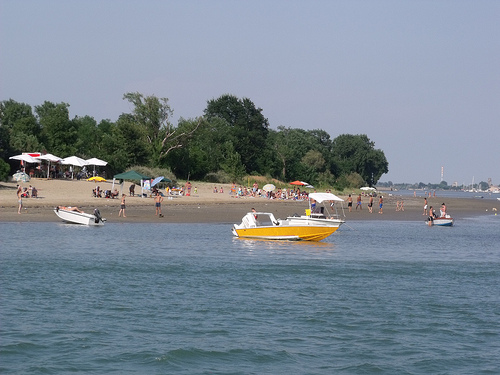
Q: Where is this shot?
A: At a beach.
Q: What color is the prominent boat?
A: Yellow.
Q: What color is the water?
A: Blue.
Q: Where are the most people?
A: On the shoreline.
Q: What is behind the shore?
A: Trees.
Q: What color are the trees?
A: Green.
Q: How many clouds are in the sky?
A: None.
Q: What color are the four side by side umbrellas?
A: White.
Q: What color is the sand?
A: Tan.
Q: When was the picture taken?
A: Daytime.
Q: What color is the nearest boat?
A: Yellow.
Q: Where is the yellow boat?
A: In the water.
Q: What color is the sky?
A: Light blue.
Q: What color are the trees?
A: Green.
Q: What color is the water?
A: Blue.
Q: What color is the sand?
A: Light brown.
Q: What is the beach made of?
A: Sand.